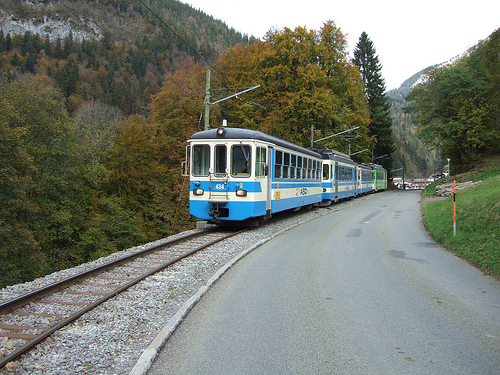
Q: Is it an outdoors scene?
A: Yes, it is outdoors.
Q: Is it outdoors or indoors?
A: It is outdoors.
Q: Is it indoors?
A: No, it is outdoors.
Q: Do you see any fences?
A: No, there are no fences.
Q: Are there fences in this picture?
A: No, there are no fences.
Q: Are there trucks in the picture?
A: No, there are no trucks.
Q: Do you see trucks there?
A: No, there are no trucks.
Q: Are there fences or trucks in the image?
A: No, there are no trucks or fences.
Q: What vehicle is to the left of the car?
A: The vehicle is a train car.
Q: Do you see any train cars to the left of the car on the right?
A: Yes, there is a train car to the left of the car.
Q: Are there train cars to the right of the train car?
A: No, the train car is to the left of the car.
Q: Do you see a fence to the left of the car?
A: No, there is a train car to the left of the car.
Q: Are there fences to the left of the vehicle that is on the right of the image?
A: No, there is a train car to the left of the car.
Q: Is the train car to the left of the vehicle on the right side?
A: Yes, the train car is to the left of the car.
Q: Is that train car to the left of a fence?
A: No, the train car is to the left of the car.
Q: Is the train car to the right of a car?
A: No, the train car is to the left of a car.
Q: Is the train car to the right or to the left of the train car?
A: The train car is to the left of the car.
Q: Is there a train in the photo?
A: Yes, there is a train.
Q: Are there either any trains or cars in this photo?
A: Yes, there is a train.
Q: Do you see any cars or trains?
A: Yes, there is a train.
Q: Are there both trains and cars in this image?
A: Yes, there are both a train and a car.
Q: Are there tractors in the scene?
A: No, there are no tractors.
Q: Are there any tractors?
A: No, there are no tractors.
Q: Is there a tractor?
A: No, there are no tractors.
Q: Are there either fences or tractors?
A: No, there are no tractors or fences.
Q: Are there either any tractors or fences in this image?
A: No, there are no tractors or fences.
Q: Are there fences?
A: No, there are no fences.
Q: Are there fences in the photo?
A: No, there are no fences.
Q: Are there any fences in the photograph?
A: No, there are no fences.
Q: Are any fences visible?
A: No, there are no fences.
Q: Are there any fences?
A: No, there are no fences.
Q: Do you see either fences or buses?
A: No, there are no fences or buses.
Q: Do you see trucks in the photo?
A: No, there are no trucks.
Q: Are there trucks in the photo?
A: No, there are no trucks.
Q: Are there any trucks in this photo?
A: No, there are no trucks.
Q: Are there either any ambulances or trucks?
A: No, there are no trucks or ambulances.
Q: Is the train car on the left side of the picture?
A: No, the car is on the right of the image.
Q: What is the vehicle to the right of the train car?
A: The vehicle is a car.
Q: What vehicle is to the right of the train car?
A: The vehicle is a car.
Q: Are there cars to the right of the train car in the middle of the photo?
A: Yes, there is a car to the right of the train car.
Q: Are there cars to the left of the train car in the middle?
A: No, the car is to the right of the train car.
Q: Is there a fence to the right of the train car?
A: No, there is a car to the right of the train car.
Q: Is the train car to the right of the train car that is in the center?
A: Yes, the car is to the right of the train car.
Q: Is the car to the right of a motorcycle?
A: No, the car is to the right of the train car.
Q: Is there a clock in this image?
A: No, there are no clocks.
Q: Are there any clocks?
A: No, there are no clocks.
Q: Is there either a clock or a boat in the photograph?
A: No, there are no clocks or boats.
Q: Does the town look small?
A: Yes, the town is small.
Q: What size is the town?
A: The town is small.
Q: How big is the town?
A: The town is small.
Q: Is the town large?
A: No, the town is small.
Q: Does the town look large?
A: No, the town is small.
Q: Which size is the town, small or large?
A: The town is small.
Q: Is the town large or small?
A: The town is small.